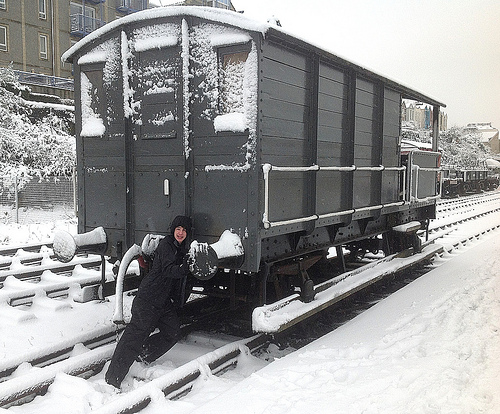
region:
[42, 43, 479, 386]
a person leaning on a train car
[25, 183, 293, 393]
this person looks like they are pushing the train car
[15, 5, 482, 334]
some parts of this photo is in black and white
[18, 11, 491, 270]
some parts of this photo is in color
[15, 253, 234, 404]
snow is covering the tracks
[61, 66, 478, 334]
this train car is parked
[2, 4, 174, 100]
a building in the background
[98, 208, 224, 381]
this person is wearing black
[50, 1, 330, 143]
snow is on the train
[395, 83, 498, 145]
structures in hte background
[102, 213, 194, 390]
person dressed in black snow suit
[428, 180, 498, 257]
train tracks with snow on them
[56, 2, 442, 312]
green train car covered in snow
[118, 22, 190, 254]
door to green train car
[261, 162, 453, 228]
silver rails on green train car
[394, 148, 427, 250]
steps to opening of front part of train car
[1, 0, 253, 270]
olive green apartment building next to train tracks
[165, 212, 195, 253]
hat covering keeping a young persons ears and head warm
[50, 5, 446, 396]
boy dressed in all black pushing on green train car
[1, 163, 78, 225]
silver metal fence surrounding yard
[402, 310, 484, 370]
footprints in the snow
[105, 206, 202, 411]
boy leaning against a train car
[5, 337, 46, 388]
snow piled on two tracks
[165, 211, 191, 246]
boy with a hood on his head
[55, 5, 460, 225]
single car of a train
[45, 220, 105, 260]
car's bumper stop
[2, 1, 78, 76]
apartment building next to the track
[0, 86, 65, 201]
snow covered tree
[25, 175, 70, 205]
brick fence near the track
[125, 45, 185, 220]
back door of the railroad car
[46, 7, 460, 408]
person pretending to push train car on tracks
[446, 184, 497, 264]
train tracks covered in snow and ice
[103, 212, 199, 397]
person wearing pants and black coat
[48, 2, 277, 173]
train covered in powdery white snow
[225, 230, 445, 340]
bottom of train car on train tracks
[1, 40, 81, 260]
tree with no leaves covered in snow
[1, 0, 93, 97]
brick building with windows and balconies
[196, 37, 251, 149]
glass window on train car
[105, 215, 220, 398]
person pretending to push the train car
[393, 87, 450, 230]
open section of train car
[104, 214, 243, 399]
A man leaning up against a train bumper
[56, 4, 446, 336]
A rail acr covered in snow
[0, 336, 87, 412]
Snow on railroad tracks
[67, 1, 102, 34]
A balcony with snow on railings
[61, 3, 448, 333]
A train car being pushed by young man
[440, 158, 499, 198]
Rail cars covered in snow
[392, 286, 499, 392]
Foot prints in the snow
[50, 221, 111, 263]
A train car bumper covered in snow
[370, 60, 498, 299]
An observation deck on a train car in winter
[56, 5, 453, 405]
A kid trying to push a train car